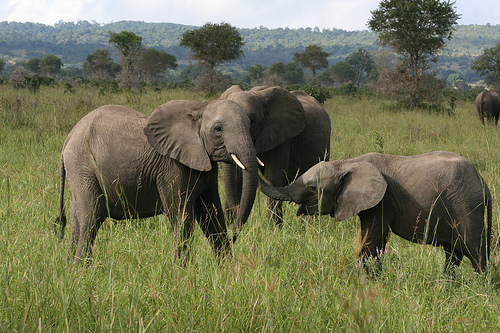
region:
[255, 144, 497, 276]
an elephant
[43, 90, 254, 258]
an huge elephant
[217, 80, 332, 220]
an huge elephant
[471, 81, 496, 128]
a huge elephant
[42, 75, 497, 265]
four huge elephants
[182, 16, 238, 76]
a huge tree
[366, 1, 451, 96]
a huge tree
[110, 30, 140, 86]
a huge tree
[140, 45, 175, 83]
a huge tree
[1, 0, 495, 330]
elephants in a forest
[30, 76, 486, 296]
adults and young elephant in grasslands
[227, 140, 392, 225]
young elephant reaching up with truck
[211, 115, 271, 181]
ivory tusks on either side of the trunk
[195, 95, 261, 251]
trunk curved in toward legs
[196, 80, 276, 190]
head of one elephant blocking face of another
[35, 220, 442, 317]
tall thin grasses covering feet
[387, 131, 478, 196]
round indentation on back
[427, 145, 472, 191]
bony lumps on back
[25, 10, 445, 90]
trees with round heads of leaves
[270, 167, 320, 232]
young elephant with mouth open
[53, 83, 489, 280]
Family of three elephants.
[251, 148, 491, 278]
smallest gray elephant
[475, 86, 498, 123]
elephant all alone facing away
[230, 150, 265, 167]
long white elephant tusks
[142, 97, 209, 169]
gray elephant ear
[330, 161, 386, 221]
gray elephant ear of small elephant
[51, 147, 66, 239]
gray elephant tail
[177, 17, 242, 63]
green tree top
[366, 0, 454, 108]
green tree top and dry bottom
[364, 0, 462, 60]
green tree top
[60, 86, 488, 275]
Three gray elephants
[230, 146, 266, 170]
Ivory elephant tusks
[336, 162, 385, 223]
Smaller elephant ear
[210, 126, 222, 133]
black right eye of elephant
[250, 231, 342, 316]
High weeds and grass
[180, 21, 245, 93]
Tall tree in distance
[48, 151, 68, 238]
Long tail of gray elephant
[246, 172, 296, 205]
Elephant trunk touching larger elephant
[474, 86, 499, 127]
Rear end of elephant in distance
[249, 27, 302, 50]
Lots of trees in distance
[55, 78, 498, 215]
there are four elephants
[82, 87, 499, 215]
the smaller elephant is looking at the larger ones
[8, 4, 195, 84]
the sky is cloudy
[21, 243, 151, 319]
the grass is tall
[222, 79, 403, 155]
the elephant is facing the camera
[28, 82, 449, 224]
only one pair of tusks are shown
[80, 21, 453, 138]
the trees are brown and green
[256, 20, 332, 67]
trees in the background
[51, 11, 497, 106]
a lot of trees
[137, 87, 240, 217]
the elephant has a big ear